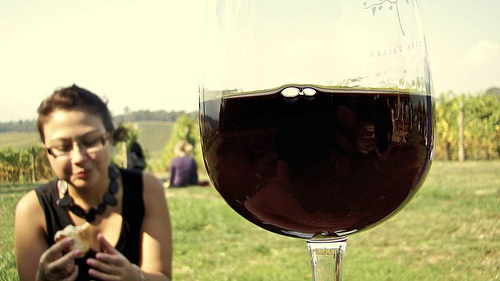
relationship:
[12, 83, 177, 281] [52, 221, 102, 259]
girl holding bread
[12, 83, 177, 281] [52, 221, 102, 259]
girl eating a bread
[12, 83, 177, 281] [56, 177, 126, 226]
girl wearing a necklace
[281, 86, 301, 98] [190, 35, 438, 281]
bubbles inside wine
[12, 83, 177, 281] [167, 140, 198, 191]
girl has hair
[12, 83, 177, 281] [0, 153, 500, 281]
girl on field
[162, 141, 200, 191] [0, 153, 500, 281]
woman on field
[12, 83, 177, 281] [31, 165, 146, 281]
girl wearing a tank top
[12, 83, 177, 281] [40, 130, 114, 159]
girl wearing glasses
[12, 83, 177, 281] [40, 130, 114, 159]
girl wearing a pair of glasses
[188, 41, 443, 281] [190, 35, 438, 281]
glass full of wine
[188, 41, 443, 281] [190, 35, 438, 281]
glass has wine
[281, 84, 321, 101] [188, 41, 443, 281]
bubbles are on top of glass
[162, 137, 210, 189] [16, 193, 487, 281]
woman on grass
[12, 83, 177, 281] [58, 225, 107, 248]
girl holding bread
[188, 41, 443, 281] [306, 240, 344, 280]
glass has stem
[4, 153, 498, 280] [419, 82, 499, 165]
field has trees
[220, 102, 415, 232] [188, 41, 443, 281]
reflection in glass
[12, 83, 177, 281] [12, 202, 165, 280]
girl looking down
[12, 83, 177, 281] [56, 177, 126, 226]
girl wearing a collar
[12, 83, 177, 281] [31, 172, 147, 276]
girl wearing a tank top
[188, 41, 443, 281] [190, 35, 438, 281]
glass for wine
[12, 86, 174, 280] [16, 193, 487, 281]
girl on grass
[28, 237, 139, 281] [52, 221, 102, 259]
hands are holding a bread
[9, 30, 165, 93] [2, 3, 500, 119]
clouds are in sky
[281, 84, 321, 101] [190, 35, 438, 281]
bubbles are in wine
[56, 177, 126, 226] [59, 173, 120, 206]
necklace around neck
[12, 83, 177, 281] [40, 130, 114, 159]
girl has glasses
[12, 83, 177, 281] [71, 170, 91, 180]
girl wearing lipstick